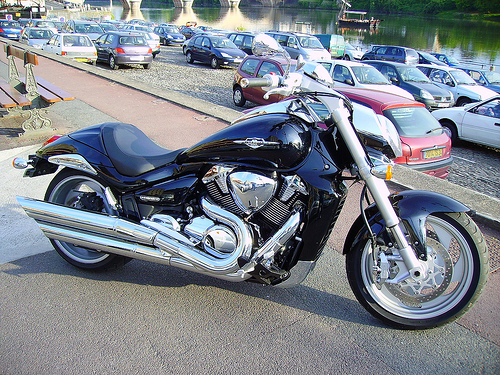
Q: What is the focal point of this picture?
A: Motorcycle.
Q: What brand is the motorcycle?
A: Harley Davidson.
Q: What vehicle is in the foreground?
A: Motorcycle.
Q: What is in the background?
A: River.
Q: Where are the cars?
A: In parking lot.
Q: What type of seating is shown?
A: Bench.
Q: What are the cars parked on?
A: Gravel.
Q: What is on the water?
A: Boat.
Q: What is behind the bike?
A: Parking lot.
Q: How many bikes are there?
A: One.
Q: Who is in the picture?
A: Nobody.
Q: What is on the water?
A: Boat.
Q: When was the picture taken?
A: Daytime.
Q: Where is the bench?
A: On the left.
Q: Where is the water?
A: In background.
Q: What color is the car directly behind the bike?
A: Red.